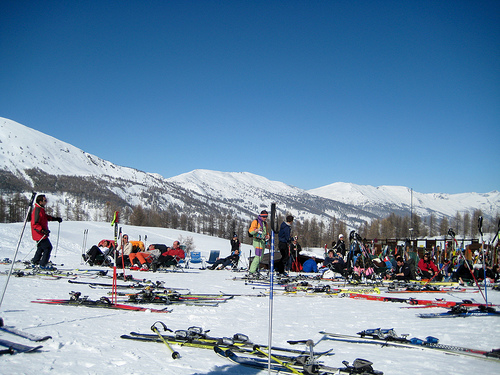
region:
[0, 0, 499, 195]
a large area of blue sky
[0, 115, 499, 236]
a mountain range in the background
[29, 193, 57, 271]
a man skiing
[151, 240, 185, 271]
a man sitting down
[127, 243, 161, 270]
a person laying down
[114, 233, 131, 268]
a person sitting down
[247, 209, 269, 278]
a person skiing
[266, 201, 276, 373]
a ski pole in the foreground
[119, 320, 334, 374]
a yellow pair of skis and ski poles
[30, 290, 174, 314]
a pair of red skis on the ground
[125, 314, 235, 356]
Pair of black skis with a yellowish green pattern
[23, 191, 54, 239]
Man with short black hair wearing a red and gray winter jacket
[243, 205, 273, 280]
Person standing wearing a colorful green and orange outfit and a purple hat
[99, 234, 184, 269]
Three people laying down in the snow in colorful winter jackets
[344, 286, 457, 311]
Red and black pair of skis lying in the snow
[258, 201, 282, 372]
Thin metal ski pole with blue rings and a black handles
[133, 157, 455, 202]
Snowy mountain peaks off in the distance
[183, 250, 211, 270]
Small blue chair standing in the white snow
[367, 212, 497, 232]
Forest of brown trees with few leaves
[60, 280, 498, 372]
Many skis and ski poles in the white snow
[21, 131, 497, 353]
a busy ski resort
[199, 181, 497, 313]
lots of people on the slopes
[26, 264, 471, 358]
skis are all over the ground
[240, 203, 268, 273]
a colorful ski suit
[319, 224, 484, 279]
a crowd of people in the snow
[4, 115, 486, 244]
mountains behind the ski slope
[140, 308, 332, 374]
yellow skis on the ground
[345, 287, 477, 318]
red skis on the ground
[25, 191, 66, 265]
a skier in a red ski jacket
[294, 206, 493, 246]
trees in the area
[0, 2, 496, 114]
blue of daytime sky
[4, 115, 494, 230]
snowy mountains on horizon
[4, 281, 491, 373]
skies sitting on snow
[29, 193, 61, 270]
man in red coat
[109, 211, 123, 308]
two red vertical poles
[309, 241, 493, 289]
group of sitting people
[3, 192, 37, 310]
tilted pole with black handle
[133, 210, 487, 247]
line of trees in front of mountains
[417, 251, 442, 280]
sitting person in red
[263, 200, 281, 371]
black top of pole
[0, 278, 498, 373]
snow skies on the snow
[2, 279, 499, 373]
ski poles and skis on the snowy ground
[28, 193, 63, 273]
a man in a red coat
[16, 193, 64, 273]
a man in a red coat holding ski poles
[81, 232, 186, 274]
four skiers lounging on chairs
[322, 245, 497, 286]
a group of skiers sitting on the ground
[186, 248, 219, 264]
two blue chairs on the ground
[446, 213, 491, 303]
two ski poles propped in the snow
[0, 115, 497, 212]
snow on the top of the mountains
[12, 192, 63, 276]
a man in a red jacket wearing skis